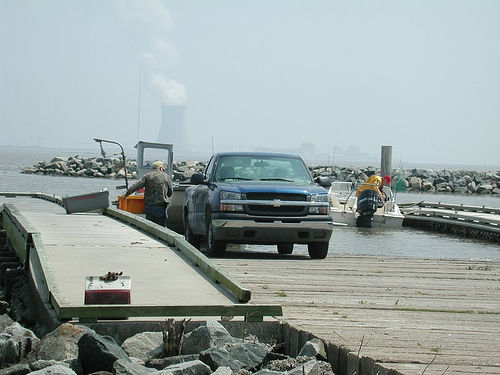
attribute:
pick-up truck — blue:
[182, 150, 333, 260]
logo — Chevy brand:
[265, 196, 288, 209]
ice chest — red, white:
[83, 270, 133, 303]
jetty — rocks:
[73, 157, 144, 180]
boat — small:
[337, 172, 409, 222]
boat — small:
[340, 180, 390, 240]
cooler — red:
[79, 291, 135, 311]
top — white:
[75, 265, 136, 290]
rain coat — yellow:
[359, 174, 390, 198]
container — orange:
[114, 184, 142, 219]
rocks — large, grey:
[68, 139, 447, 192]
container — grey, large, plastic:
[58, 188, 108, 223]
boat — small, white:
[344, 174, 411, 240]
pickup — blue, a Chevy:
[181, 144, 332, 254]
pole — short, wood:
[372, 144, 399, 194]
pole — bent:
[92, 123, 135, 184]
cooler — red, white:
[69, 253, 166, 330]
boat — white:
[327, 169, 399, 245]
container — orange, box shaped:
[119, 179, 150, 224]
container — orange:
[119, 191, 156, 224]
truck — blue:
[168, 135, 321, 245]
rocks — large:
[52, 146, 437, 187]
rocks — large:
[25, 139, 232, 192]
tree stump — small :
[160, 316, 193, 356]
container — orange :
[117, 194, 147, 214]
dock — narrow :
[399, 201, 498, 241]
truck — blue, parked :
[180, 151, 333, 258]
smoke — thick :
[111, 0, 190, 103]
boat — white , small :
[327, 179, 404, 229]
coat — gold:
[354, 176, 380, 195]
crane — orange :
[117, 193, 147, 214]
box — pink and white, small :
[82, 275, 132, 319]